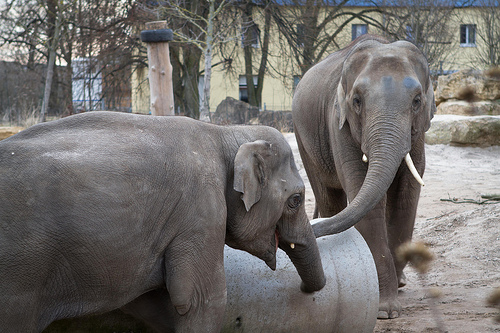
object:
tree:
[361, 0, 457, 81]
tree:
[230, 1, 270, 107]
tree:
[466, 10, 499, 71]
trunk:
[302, 96, 414, 238]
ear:
[231, 140, 274, 212]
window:
[350, 20, 367, 46]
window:
[297, 23, 317, 46]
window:
[238, 21, 259, 48]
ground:
[389, 95, 442, 147]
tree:
[144, 0, 265, 121]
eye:
[412, 96, 421, 108]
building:
[133, 0, 500, 117]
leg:
[329, 114, 402, 299]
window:
[238, 70, 260, 103]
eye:
[287, 192, 303, 209]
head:
[332, 40, 439, 188]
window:
[458, 20, 480, 46]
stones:
[429, 62, 499, 149]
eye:
[351, 97, 364, 112]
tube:
[161, 216, 384, 331]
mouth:
[274, 225, 292, 273]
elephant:
[0, 110, 329, 332]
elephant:
[289, 36, 438, 319]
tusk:
[360, 153, 426, 188]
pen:
[3, 5, 495, 327]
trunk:
[280, 220, 324, 291]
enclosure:
[1, 12, 500, 332]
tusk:
[289, 241, 295, 248]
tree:
[251, 1, 365, 106]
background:
[1, 1, 481, 114]